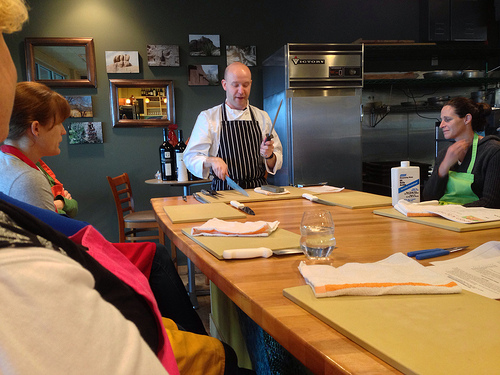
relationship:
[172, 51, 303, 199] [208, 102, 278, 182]
man has apron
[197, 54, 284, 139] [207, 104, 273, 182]
chef with apron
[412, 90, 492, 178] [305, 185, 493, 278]
woman sitting at a table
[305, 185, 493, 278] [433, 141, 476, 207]
table with a apron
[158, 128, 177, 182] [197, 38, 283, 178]
bottle behind a chef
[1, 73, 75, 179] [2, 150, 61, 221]
woman in shirt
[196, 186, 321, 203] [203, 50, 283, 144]
board in front of a chef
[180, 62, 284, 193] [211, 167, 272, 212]
chef holding knife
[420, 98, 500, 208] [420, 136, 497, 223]
woman in an apron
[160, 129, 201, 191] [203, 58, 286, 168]
bottle behind man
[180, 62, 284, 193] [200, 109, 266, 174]
chef in apron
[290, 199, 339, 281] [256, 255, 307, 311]
glass on table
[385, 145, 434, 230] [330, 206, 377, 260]
bottle on table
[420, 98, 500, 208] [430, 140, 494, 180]
woman in shirt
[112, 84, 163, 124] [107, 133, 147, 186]
lights on wall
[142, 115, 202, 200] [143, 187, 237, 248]
bottle on table